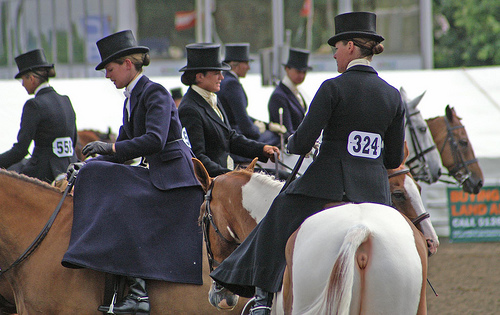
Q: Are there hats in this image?
A: Yes, there is a hat.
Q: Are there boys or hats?
A: Yes, there is a hat.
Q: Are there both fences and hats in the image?
A: No, there is a hat but no fences.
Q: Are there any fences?
A: No, there are no fences.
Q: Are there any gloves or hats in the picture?
A: Yes, there is a hat.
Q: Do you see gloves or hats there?
A: Yes, there is a hat.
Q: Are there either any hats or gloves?
A: Yes, there is a hat.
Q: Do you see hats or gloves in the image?
A: Yes, there is a hat.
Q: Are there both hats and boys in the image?
A: No, there is a hat but no boys.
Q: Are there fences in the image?
A: No, there are no fences.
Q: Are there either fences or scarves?
A: No, there are no fences or scarves.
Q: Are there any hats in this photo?
A: Yes, there is a hat.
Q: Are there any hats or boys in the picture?
A: Yes, there is a hat.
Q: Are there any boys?
A: No, there are no boys.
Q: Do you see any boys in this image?
A: No, there are no boys.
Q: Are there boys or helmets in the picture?
A: No, there are no boys or helmets.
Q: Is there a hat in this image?
A: Yes, there is a hat.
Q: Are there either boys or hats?
A: Yes, there is a hat.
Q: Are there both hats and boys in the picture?
A: No, there is a hat but no boys.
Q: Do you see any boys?
A: No, there are no boys.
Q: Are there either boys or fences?
A: No, there are no boys or fences.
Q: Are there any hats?
A: Yes, there is a hat.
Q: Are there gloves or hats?
A: Yes, there is a hat.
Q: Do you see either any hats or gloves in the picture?
A: Yes, there is a hat.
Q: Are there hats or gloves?
A: Yes, there is a hat.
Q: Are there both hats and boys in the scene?
A: No, there is a hat but no boys.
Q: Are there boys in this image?
A: No, there are no boys.